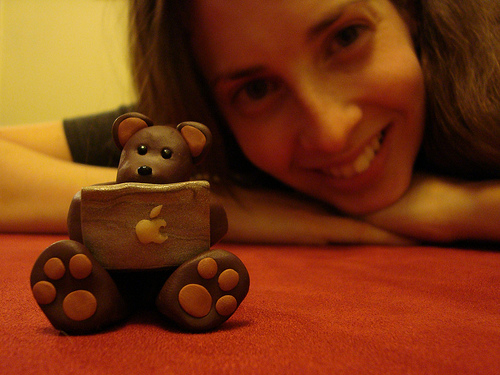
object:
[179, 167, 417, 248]
hands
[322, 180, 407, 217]
chin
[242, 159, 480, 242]
hands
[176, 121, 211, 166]
ceramic ear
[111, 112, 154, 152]
ceramic ear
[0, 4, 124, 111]
wall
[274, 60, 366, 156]
nose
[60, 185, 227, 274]
cover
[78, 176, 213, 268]
tablet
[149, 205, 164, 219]
leaf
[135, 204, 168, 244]
apple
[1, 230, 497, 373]
fabric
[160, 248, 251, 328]
feet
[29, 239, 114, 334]
big feet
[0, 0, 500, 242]
girl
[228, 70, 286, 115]
eye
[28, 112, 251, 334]
bear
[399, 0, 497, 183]
hair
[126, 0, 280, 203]
hair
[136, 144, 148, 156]
beady eyes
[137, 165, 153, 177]
black nose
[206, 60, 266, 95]
eyebrow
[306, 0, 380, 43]
eyebrow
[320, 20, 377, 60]
eye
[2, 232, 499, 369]
red surface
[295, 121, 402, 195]
mouth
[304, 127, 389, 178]
teeth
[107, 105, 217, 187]
head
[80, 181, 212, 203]
edge